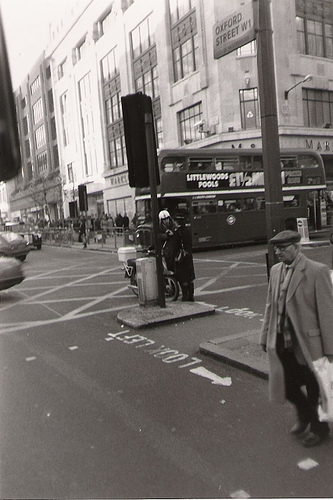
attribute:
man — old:
[263, 230, 331, 446]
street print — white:
[106, 331, 233, 406]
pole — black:
[251, 1, 289, 237]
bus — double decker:
[133, 147, 329, 254]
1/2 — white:
[239, 170, 255, 189]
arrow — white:
[187, 360, 238, 407]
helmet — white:
[152, 205, 170, 222]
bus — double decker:
[153, 137, 322, 228]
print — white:
[99, 324, 158, 351]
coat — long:
[173, 223, 195, 285]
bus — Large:
[159, 147, 321, 227]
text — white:
[196, 180, 216, 188]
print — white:
[183, 172, 229, 188]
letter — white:
[105, 326, 129, 336]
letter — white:
[115, 328, 140, 343]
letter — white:
[121, 333, 147, 345]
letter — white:
[133, 337, 156, 348]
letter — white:
[143, 342, 170, 354]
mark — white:
[106, 327, 130, 338]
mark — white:
[103, 336, 113, 341]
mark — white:
[115, 329, 139, 340]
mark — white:
[187, 363, 232, 387]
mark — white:
[161, 348, 187, 363]